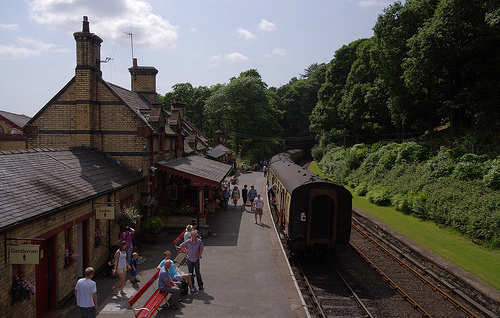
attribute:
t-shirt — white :
[74, 278, 97, 305]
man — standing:
[181, 229, 204, 294]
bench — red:
[125, 253, 193, 316]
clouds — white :
[121, 6, 255, 70]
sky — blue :
[148, 6, 365, 78]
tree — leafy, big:
[201, 66, 289, 171]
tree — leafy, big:
[155, 81, 226, 132]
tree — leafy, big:
[270, 74, 320, 144]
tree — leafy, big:
[308, 37, 372, 144]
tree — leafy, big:
[397, 0, 497, 135]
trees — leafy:
[295, 24, 499, 224]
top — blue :
[151, 260, 196, 292]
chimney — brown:
[66, 20, 128, 88]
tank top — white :
[113, 247, 128, 269]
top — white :
[113, 249, 127, 272]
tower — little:
[71, 14, 103, 76]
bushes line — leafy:
[313, 141, 498, 240]